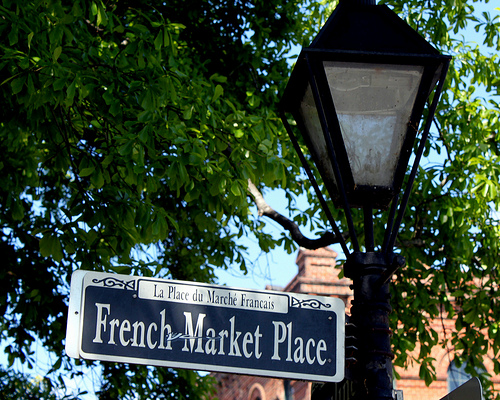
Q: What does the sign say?
A: French market place.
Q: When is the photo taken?
A: Daylight.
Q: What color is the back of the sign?
A: White.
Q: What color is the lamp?
A: Black.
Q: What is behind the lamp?
A: Tree.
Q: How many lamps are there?
A: One.